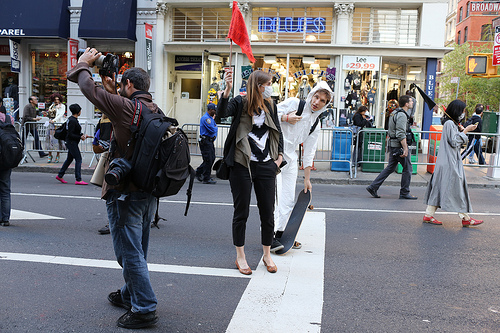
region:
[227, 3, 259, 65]
A red flag.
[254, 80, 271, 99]
A white hospital mask.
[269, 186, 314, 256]
A black skateboard.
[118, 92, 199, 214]
A black backpack.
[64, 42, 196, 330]
A man holding a camera.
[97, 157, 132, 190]
A black camera.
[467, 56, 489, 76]
A crosswalk signal.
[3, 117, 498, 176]
A metal fence.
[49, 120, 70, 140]
A black pocketbook.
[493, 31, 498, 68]
Red and white street signs.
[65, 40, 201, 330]
guy wearing a brown long sleeve shirt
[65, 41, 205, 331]
guy wearing blue denim jeans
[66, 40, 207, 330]
guy wearing black tennis shoes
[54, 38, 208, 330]
guy wearing black backpack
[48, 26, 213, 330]
guy taking pictures with a camera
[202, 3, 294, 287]
lady holding a red flag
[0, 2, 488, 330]
people in the street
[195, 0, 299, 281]
lady wearing a mask over her mouth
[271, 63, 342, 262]
guy holding a skateboard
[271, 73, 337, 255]
guy dressed in all white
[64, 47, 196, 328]
Man takes a photograph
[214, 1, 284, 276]
Woman with a mask holds up a red flag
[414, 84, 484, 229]
Woman props a black flag on her shoulder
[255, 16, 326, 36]
Blue neon sign hang in the window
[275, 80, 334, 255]
Boy in white holds a skateboard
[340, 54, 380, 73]
Sign advertising prices hangs overhead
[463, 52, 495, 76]
The no walk sign is alight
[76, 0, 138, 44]
Black awning over the window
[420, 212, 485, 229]
Pair of red shoes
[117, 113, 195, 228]
Black backpack is slightly open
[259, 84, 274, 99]
white mask over a woman's mouth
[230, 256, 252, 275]
brown shoe on a woman's foot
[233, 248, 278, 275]
brown shoes on a woman's feet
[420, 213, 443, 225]
red shoe on a woman's foot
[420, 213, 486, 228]
red shoes on a woman's feet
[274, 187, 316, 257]
black skateboard in a man's hand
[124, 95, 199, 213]
large black backpack on a man's back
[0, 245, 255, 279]
thick white line on a street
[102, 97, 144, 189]
camera hanging around off of a man's shoulder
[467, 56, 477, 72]
red stop hand signal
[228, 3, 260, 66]
a red flag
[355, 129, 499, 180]
a long gray gate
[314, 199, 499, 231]
a long white line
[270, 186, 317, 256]
a black skateboard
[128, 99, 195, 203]
a large black backpack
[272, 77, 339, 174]
a white hooded shirt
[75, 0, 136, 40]
a small blue canopy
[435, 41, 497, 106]
a large green tree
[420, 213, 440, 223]
a woman's red shoe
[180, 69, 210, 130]
a white door of a building